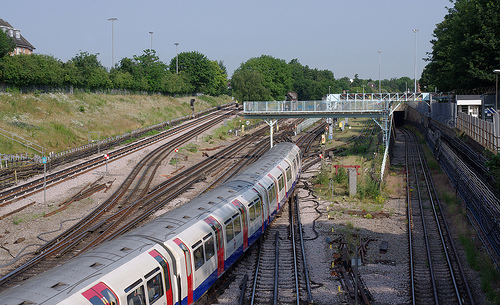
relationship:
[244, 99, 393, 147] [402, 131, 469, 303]
bridge over track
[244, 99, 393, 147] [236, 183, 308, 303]
bridge over track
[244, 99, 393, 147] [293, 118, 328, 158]
bridge over track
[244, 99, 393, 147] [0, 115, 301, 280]
bridge over track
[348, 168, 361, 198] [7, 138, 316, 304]
pole by train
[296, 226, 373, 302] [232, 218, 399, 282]
rocks on side of train tracks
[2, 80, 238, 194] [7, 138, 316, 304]
hill to left of train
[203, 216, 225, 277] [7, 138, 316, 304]
door of train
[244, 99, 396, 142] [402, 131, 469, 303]
bridge over track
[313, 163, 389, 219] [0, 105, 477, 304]
green vegetation growing by train tracks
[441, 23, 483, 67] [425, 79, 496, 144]
green tree to right of train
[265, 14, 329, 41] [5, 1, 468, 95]
white clouds in sky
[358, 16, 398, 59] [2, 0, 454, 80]
clouds in blue sky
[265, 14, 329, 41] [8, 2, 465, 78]
white clouds in sky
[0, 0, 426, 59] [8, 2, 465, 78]
clouds in sky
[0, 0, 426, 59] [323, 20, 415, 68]
clouds in sky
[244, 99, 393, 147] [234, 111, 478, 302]
bridge above tracks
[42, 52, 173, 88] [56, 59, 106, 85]
trees with green leaves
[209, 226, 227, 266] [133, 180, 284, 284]
door of train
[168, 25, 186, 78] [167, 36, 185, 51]
pole with light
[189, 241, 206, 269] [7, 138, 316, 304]
window on side of train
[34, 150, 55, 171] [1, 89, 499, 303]
sign visible on ground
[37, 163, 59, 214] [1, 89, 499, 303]
post visible on ground